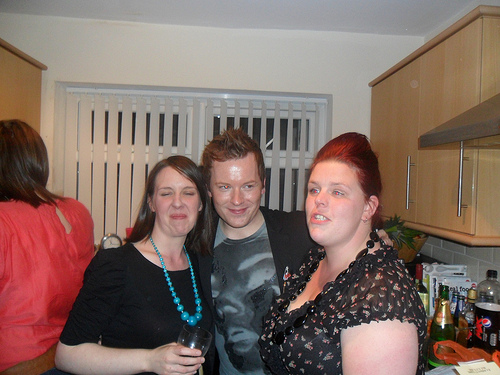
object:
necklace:
[162, 254, 206, 327]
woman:
[63, 154, 218, 374]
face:
[159, 169, 197, 230]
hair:
[311, 135, 382, 233]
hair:
[0, 117, 66, 207]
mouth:
[166, 215, 184, 225]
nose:
[169, 194, 184, 207]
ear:
[147, 193, 153, 214]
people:
[3, 115, 458, 359]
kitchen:
[17, 10, 500, 367]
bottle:
[427, 285, 453, 367]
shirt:
[0, 196, 94, 358]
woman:
[4, 118, 96, 370]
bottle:
[474, 268, 499, 351]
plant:
[383, 217, 412, 247]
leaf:
[390, 219, 410, 244]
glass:
[174, 323, 213, 369]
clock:
[96, 233, 121, 252]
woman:
[262, 131, 427, 374]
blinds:
[81, 103, 314, 185]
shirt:
[209, 228, 297, 374]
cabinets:
[366, 37, 489, 246]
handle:
[399, 151, 416, 212]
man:
[202, 131, 316, 372]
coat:
[258, 204, 316, 292]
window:
[72, 97, 321, 250]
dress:
[59, 241, 220, 374]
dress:
[256, 245, 428, 373]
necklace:
[278, 272, 341, 336]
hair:
[202, 133, 269, 187]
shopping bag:
[432, 341, 499, 366]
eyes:
[157, 188, 197, 198]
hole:
[52, 201, 75, 232]